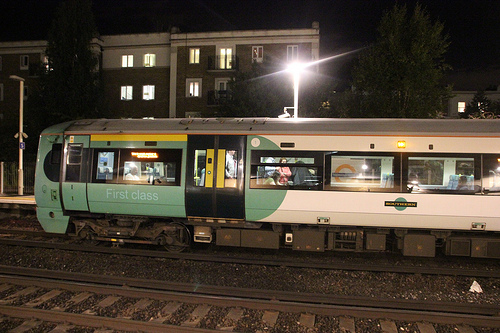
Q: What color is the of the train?
A: White and green.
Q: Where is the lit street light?
A: Between the train and building.